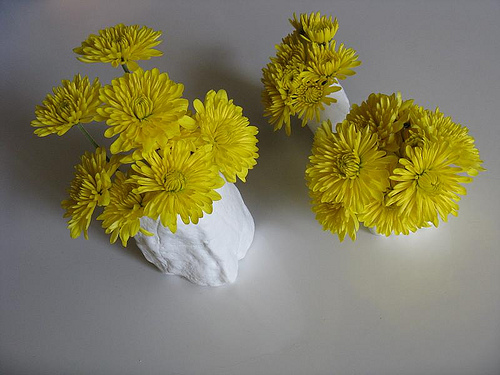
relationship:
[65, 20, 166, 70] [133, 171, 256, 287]
yellow flower in container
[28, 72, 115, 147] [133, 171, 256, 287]
yellow flower in container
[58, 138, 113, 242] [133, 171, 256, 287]
yellow flower in container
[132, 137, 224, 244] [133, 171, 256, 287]
yellow flower in container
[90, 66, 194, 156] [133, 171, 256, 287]
yellow flower in container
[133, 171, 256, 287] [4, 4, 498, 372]
container on table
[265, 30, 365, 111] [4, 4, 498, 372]
vase on table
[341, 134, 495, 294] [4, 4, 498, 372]
vase on table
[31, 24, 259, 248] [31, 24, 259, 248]
flowers in flowers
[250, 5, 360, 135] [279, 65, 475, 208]
flowers behind flowers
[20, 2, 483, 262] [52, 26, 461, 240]
flowers behind group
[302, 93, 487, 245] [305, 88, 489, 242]
flower in group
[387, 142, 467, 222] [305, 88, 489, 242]
flower in group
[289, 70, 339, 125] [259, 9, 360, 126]
flower in group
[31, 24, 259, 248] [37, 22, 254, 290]
flowers in group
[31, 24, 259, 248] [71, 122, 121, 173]
flowers has stem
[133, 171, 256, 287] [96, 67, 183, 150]
container has flowers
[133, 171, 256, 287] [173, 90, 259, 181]
container has flowers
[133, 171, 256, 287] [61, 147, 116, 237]
container has flowers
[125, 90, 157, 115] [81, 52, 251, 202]
middle to flower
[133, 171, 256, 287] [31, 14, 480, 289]
container with flowers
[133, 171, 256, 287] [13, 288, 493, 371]
container on background